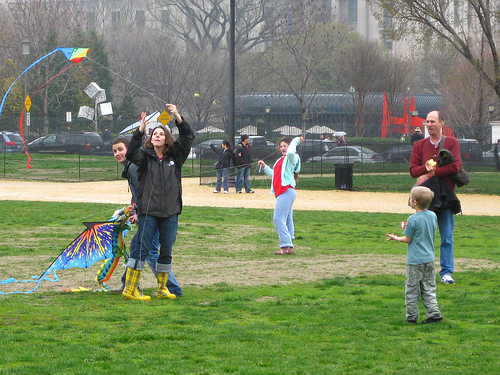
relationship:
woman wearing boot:
[119, 89, 187, 308] [119, 266, 151, 300]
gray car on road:
[310, 141, 376, 163] [37, 131, 497, 164]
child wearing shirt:
[386, 185, 448, 322] [401, 209, 436, 264]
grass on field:
[2, 154, 497, 374] [2, 153, 497, 374]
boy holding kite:
[383, 182, 441, 322] [0, 43, 91, 168]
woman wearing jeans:
[256, 125, 313, 269] [207, 163, 235, 201]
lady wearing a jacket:
[118, 96, 191, 305] [123, 119, 196, 222]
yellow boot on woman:
[155, 268, 177, 299] [121, 100, 196, 302]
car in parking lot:
[288, 115, 388, 215] [205, 52, 474, 172]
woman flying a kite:
[119, 89, 187, 308] [6, 36, 101, 114]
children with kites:
[99, 124, 454, 319] [14, 40, 110, 166]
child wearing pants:
[386, 185, 448, 322] [128, 213, 174, 270]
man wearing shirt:
[406, 101, 460, 289] [407, 105, 465, 287]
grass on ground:
[2, 203, 500, 371] [301, 194, 382, 262]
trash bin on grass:
[333, 161, 353, 191] [203, 172, 499, 195]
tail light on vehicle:
[81, 140, 89, 150] [25, 129, 108, 154]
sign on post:
[62, 109, 73, 124] [69, 140, 89, 181]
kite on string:
[47, 36, 102, 70] [78, 49, 170, 111]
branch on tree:
[455, 36, 475, 64] [375, 1, 496, 94]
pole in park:
[226, 2, 236, 191] [2, 151, 498, 373]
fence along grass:
[357, 144, 403, 174] [309, 212, 378, 253]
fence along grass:
[357, 144, 400, 193] [7, 300, 239, 352]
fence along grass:
[357, 144, 400, 193] [0, 205, 55, 253]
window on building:
[347, 2, 359, 29] [109, 1, 495, 90]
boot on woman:
[119, 266, 151, 300] [123, 103, 190, 300]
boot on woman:
[153, 271, 178, 300] [123, 103, 190, 300]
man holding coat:
[406, 101, 460, 289] [357, 76, 496, 218]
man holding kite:
[406, 101, 460, 289] [47, 39, 86, 63]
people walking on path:
[236, 131, 253, 191] [0, 176, 497, 216]